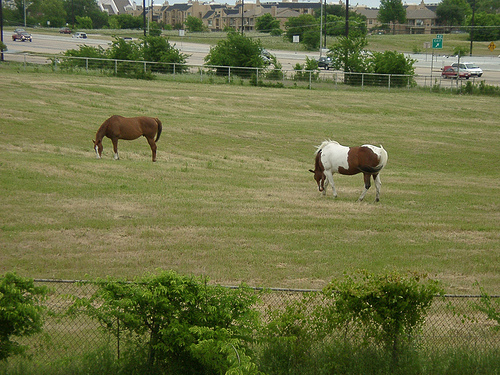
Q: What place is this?
A: It is a field.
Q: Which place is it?
A: It is a field.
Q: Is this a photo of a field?
A: Yes, it is showing a field.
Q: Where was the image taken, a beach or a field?
A: It was taken at a field.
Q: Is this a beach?
A: No, it is a field.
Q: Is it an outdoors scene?
A: Yes, it is outdoors.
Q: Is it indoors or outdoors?
A: It is outdoors.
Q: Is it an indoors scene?
A: No, it is outdoors.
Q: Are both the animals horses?
A: Yes, all the animals are horses.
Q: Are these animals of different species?
A: No, all the animals are horses.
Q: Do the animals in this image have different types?
A: No, all the animals are horses.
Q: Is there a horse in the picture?
A: Yes, there is a horse.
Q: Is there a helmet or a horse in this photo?
A: Yes, there is a horse.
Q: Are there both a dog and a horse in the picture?
A: No, there is a horse but no dogs.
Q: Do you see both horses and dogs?
A: No, there is a horse but no dogs.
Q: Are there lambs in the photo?
A: No, there are no lambs.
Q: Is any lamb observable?
A: No, there are no lambs.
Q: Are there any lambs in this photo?
A: No, there are no lambs.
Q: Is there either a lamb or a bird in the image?
A: No, there are no lambs or birds.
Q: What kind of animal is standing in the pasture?
A: The animal is a horse.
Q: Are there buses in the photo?
A: No, there are no buses.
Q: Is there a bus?
A: No, there are no buses.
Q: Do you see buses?
A: No, there are no buses.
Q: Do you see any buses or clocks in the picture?
A: No, there are no buses or clocks.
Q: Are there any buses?
A: No, there are no buses.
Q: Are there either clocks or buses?
A: No, there are no buses or clocks.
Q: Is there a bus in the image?
A: No, there are no buses.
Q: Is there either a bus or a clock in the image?
A: No, there are no buses or clocks.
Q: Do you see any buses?
A: No, there are no buses.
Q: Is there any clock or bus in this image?
A: No, there are no buses or clocks.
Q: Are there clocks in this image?
A: No, there are no clocks.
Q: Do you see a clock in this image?
A: No, there are no clocks.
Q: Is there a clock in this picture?
A: No, there are no clocks.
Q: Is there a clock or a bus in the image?
A: No, there are no clocks or buses.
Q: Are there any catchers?
A: No, there are no catchers.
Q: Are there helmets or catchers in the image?
A: No, there are no catchers or helmets.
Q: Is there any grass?
A: Yes, there is grass.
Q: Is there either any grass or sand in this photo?
A: Yes, there is grass.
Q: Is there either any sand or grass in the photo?
A: Yes, there is grass.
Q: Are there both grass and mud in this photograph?
A: No, there is grass but no mud.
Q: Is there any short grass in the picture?
A: Yes, there is short grass.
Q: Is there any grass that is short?
A: Yes, there is grass that is short.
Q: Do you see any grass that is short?
A: Yes, there is grass that is short.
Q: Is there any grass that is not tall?
A: Yes, there is short grass.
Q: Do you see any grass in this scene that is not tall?
A: Yes, there is short grass.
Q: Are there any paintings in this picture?
A: No, there are no paintings.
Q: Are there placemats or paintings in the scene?
A: No, there are no paintings or placemats.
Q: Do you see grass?
A: Yes, there is grass.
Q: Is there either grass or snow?
A: Yes, there is grass.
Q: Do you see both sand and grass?
A: No, there is grass but no sand.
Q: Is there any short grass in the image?
A: Yes, there is short grass.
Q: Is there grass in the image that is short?
A: Yes, there is grass that is short.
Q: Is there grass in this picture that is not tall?
A: Yes, there is short grass.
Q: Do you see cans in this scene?
A: No, there are no cans.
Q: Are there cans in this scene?
A: No, there are no cans.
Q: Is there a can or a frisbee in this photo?
A: No, there are no cans or frisbees.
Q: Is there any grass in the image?
A: Yes, there is grass.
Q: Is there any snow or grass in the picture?
A: Yes, there is grass.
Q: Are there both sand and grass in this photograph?
A: No, there is grass but no sand.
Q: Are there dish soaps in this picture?
A: No, there are no dish soaps.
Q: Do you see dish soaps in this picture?
A: No, there are no dish soaps.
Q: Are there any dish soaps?
A: No, there are no dish soaps.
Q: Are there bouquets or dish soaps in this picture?
A: No, there are no dish soaps or bouquets.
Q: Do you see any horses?
A: Yes, there is a horse.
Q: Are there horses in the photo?
A: Yes, there is a horse.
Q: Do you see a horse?
A: Yes, there is a horse.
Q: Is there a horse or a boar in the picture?
A: Yes, there is a horse.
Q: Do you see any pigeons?
A: No, there are no pigeons.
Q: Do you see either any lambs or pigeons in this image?
A: No, there are no pigeons or lambs.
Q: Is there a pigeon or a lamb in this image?
A: No, there are no pigeons or lambs.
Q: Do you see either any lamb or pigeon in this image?
A: No, there are no pigeons or lambs.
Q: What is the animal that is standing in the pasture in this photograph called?
A: The animal is a horse.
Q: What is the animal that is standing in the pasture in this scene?
A: The animal is a horse.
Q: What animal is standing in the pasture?
A: The animal is a horse.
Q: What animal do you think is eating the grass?
A: The horse is eating the grass.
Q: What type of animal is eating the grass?
A: The animal is a horse.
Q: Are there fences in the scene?
A: Yes, there is a fence.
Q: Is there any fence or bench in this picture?
A: Yes, there is a fence.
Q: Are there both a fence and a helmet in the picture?
A: No, there is a fence but no helmets.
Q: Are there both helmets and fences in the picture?
A: No, there is a fence but no helmets.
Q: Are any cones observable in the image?
A: No, there are no cones.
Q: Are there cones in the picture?
A: No, there are no cones.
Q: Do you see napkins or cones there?
A: No, there are no cones or napkins.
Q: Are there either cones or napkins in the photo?
A: No, there are no cones or napkins.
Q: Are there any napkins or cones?
A: No, there are no cones or napkins.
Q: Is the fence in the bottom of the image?
A: Yes, the fence is in the bottom of the image.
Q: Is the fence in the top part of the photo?
A: No, the fence is in the bottom of the image.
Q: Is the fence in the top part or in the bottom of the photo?
A: The fence is in the bottom of the image.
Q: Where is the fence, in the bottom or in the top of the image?
A: The fence is in the bottom of the image.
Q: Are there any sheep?
A: No, there are no sheep.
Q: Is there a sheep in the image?
A: No, there is no sheep.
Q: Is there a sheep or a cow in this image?
A: No, there are no sheep or cows.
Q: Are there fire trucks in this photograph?
A: No, there are no fire trucks.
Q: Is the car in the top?
A: Yes, the car is in the top of the image.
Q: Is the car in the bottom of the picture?
A: No, the car is in the top of the image.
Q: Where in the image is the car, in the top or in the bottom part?
A: The car is in the top of the image.